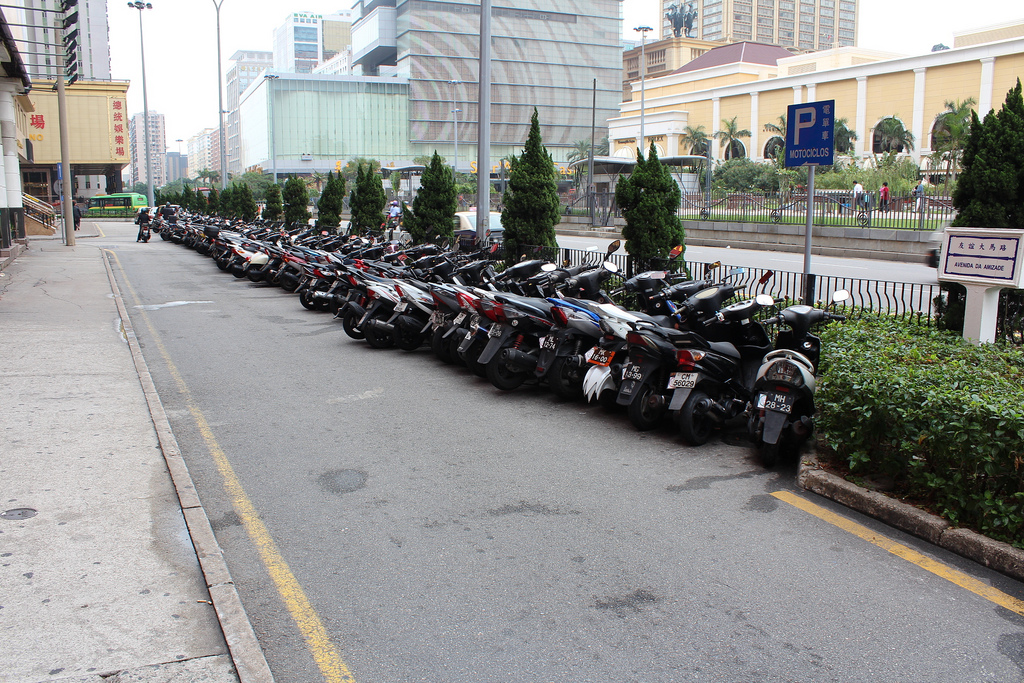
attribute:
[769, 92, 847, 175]
sign — blue, white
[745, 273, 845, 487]
bike — black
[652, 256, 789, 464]
bike — black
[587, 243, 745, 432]
bike — black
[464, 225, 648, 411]
bike — black